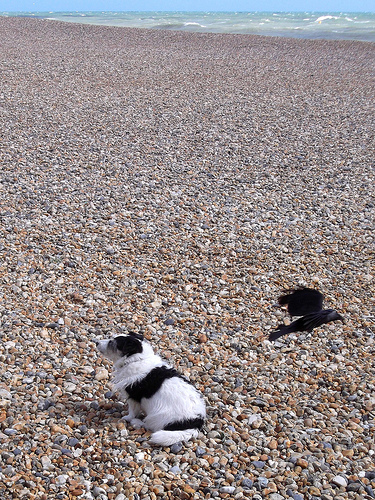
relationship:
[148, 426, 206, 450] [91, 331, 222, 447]
tail on dog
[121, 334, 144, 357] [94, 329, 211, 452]
ear on dog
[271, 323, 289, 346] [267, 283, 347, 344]
tail on bird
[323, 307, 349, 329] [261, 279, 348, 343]
head on bird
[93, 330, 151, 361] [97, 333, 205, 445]
head on dog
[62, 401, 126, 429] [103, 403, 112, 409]
shadow on a rock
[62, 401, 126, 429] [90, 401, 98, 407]
shadow on a rock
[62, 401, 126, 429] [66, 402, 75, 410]
shadow on a rock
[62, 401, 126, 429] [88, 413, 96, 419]
shadow on a rock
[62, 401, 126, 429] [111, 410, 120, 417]
shadow on a rock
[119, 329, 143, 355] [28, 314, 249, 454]
ears on a dog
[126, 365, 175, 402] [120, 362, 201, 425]
stripe on back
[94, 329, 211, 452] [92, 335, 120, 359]
dog has face